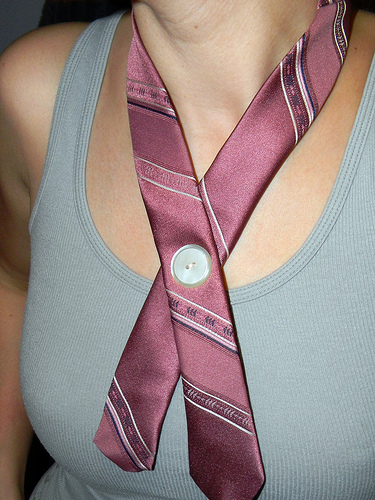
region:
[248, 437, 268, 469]
edge if a tie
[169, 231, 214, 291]
the button is round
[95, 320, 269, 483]
the tie is purple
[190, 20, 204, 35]
a freckle is on her neck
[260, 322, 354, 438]
the shirt is green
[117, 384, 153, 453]
the stripe is white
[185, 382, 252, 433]
the stripe is on the tie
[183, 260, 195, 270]
the thread is white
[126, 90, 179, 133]
the stripe is blue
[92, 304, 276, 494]
the tie is satin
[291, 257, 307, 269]
the collar is stitched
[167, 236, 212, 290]
a large white butteon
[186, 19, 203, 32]
a freckle on a neck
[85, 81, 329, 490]
a pink silk tie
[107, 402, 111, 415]
a thin blue stripe on the tie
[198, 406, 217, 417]
a thin white stripe on a tie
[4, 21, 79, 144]
a bare shoulder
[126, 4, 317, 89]
a thin white neck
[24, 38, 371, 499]
a green tank top covering a bosom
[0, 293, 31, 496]
an arm on a woman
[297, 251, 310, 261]
gray stitching in the tank top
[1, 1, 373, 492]
A woman in the foreground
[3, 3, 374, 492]
Woman is wearing a tank top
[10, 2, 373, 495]
Tank top is gray in color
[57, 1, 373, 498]
Woman is wearing a tie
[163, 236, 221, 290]
Tie has a button on it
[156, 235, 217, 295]
Button on the tie is clear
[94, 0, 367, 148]
Tie is around woman's neck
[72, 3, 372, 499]
The tie is pink in color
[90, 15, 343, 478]
Tie has white and blue colored stripes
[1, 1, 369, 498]
A view of a woman's neck and upper body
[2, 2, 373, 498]
woman in gray tank top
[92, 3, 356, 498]
purple tie around neck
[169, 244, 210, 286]
round white plastic button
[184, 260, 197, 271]
thread in two holes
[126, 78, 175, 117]
white and blue stripes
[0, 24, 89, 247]
shoulder in sleeveless shirt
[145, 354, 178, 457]
light reflection on tie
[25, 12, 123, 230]
strap of tank top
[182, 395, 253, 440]
white line on purple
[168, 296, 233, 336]
blue design on tie